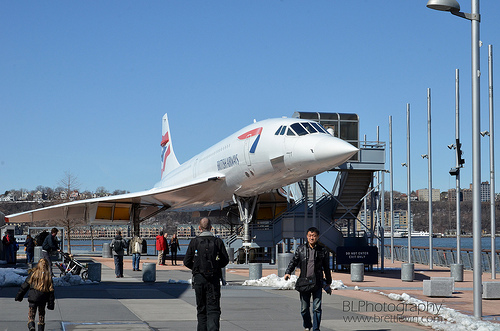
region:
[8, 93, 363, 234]
a British SST jet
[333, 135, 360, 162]
the nosecone of a jet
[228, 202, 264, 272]
the nose gear of a jet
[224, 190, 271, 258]
the landing gear of a jet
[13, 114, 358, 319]
people under the display of a jet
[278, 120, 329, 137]
the cockpit of a jet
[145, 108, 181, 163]
the tail-fin of a jet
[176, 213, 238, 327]
a man dressed in black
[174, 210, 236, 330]
a man wearing a black backpack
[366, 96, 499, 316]
a row of empty flag poles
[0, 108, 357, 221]
it is a airplane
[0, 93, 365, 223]
airplane color is white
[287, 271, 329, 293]
man having shoulder bag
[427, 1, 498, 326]
it is lamp post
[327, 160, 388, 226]
it is a airplane ladder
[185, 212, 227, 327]
man wearing black color cote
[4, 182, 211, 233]
it is airplane wing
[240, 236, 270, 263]
it is airplane wheel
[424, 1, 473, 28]
it is a lamp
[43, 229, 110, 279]
man holding the trolley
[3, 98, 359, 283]
a jet is on display on a tarmac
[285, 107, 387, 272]
a metal staircase is next to the plane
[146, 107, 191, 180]
the tail of the plane is white with stripes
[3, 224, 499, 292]
a fence is around the jet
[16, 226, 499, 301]
a waterway is behind the jet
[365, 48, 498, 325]
steel poles are standing on a sidewalk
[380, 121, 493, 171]
lights are on the poles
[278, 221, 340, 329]
a man is walking away from the plane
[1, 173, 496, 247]
buildings are on the other side of the river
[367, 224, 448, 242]
boats are moored on the river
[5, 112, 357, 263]
A big white airplane.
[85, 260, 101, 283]
A trash can on the ground.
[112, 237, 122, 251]
A backpack on a mans back.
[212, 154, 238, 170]
The name of the airline.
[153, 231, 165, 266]
A man in a red jacket.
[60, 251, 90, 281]
A man pushing a stroller.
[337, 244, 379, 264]
A sign with words on it.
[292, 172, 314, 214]
A stairway going up to plane.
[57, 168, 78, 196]
A tree with out leafs.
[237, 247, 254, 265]
The landing ties of the plane.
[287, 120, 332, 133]
WINDOWS ON THE PLANE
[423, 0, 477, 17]
LIGHT ON THE POLE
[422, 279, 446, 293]
CEMENT BLOCK ON THE GROUND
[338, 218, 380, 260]
STEPS ON THE SIDE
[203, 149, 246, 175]
NUMBERS IN BLACK ON THE SIDE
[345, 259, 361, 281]
TRASH CAN ON THE SIDE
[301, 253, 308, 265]
MAN WEARING A BLACK JACKET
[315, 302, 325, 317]
MAN HAS ON BLUE JEANS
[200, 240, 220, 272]
MAN CARING A BAG ON BACK